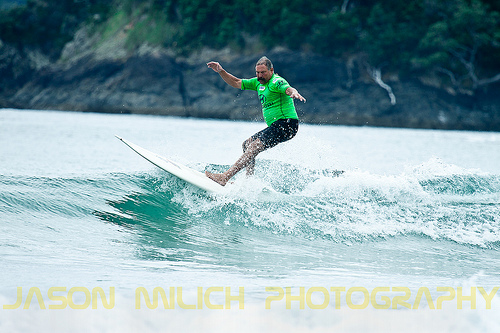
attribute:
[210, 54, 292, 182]
man — surfing, surfer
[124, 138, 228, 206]
surfboard — white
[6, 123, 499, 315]
ocean — blue, clear, white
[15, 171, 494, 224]
wave — green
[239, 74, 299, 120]
shirt — green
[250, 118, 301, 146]
shorts — black, blue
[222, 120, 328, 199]
water — spraying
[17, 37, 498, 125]
cliff — rocky, exposed, rocks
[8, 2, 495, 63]
trees — green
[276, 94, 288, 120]
stripe — black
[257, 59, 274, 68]
hair — brown, wet